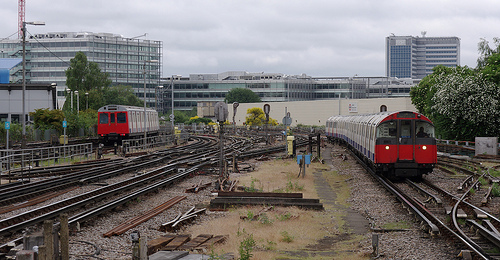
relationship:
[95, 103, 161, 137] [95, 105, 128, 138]
train has front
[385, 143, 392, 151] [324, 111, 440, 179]
headlight attached to train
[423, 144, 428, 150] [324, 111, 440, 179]
headlight attached to train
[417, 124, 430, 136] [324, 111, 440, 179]
conductor inside train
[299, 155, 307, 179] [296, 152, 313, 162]
post supporting sign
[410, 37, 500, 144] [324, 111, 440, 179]
trees to right of train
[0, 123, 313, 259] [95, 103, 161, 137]
tracks to right of train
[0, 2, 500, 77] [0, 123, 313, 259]
sky above tracks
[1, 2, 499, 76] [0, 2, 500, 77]
clouds floating in sky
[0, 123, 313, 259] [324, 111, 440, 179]
tracks to left of train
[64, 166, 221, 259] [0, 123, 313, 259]
gravel next to tracks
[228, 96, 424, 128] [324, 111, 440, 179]
wall behind train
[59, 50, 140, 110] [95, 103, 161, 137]
trees to left of train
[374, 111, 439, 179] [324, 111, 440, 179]
front of train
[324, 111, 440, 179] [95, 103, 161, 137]
train to right of train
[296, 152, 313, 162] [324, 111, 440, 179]
sign to left of train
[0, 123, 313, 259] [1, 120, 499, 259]
tracks in middle of train yard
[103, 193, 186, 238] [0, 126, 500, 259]
slat lying on ground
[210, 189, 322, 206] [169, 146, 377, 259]
slats lying in dirt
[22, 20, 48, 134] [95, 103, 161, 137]
light pole to left of train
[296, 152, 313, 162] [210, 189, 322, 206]
sign behind slats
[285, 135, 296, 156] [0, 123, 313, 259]
pole to right of tracks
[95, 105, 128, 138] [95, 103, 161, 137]
front of train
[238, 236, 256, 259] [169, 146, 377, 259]
grass growing in dirt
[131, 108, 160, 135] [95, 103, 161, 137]
edge of train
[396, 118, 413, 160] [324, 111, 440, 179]
door attached to train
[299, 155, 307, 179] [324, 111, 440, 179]
post to left of train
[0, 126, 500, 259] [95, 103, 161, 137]
ground beneath train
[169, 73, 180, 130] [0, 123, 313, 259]
post next to tracks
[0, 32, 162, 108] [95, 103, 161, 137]
building to left of train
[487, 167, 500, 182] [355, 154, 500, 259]
grass between tracks